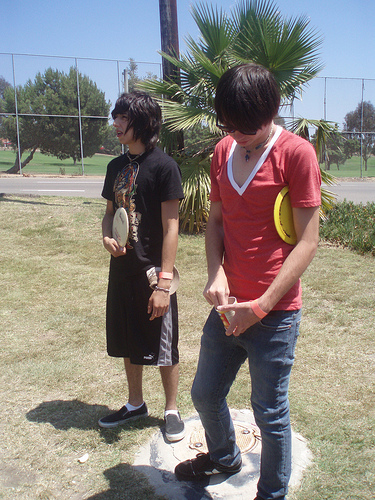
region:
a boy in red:
[209, 181, 305, 498]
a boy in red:
[220, 282, 350, 487]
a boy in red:
[209, 208, 272, 336]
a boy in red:
[224, 211, 275, 416]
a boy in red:
[239, 237, 293, 494]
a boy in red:
[245, 157, 271, 319]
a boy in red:
[184, 146, 282, 367]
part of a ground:
[305, 448, 326, 464]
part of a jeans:
[256, 458, 274, 481]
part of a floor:
[179, 474, 199, 492]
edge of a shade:
[60, 406, 106, 450]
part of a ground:
[29, 428, 58, 452]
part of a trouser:
[203, 374, 224, 408]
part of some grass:
[327, 385, 370, 416]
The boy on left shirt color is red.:
[211, 129, 313, 313]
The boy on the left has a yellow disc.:
[268, 182, 313, 245]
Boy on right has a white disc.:
[101, 204, 137, 255]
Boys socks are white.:
[123, 395, 145, 411]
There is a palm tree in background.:
[139, 31, 334, 231]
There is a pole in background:
[151, 2, 197, 164]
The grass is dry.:
[1, 236, 352, 497]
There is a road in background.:
[0, 162, 370, 203]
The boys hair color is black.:
[115, 66, 276, 124]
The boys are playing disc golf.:
[2, 27, 366, 475]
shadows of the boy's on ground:
[97, 358, 198, 493]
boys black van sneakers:
[76, 397, 185, 445]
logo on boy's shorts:
[134, 348, 154, 372]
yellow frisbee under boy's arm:
[265, 174, 307, 269]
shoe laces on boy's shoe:
[192, 444, 212, 465]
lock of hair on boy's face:
[118, 117, 135, 138]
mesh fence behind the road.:
[1, 71, 109, 143]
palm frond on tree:
[255, 15, 322, 79]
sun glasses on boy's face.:
[212, 120, 260, 137]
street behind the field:
[0, 169, 78, 196]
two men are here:
[76, 45, 327, 267]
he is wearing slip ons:
[71, 353, 242, 458]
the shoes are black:
[98, 383, 250, 481]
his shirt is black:
[57, 49, 169, 424]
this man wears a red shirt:
[200, 92, 341, 300]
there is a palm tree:
[101, 36, 334, 206]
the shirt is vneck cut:
[168, 42, 355, 372]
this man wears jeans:
[182, 270, 357, 447]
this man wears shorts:
[47, 260, 193, 388]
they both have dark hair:
[84, 54, 336, 285]